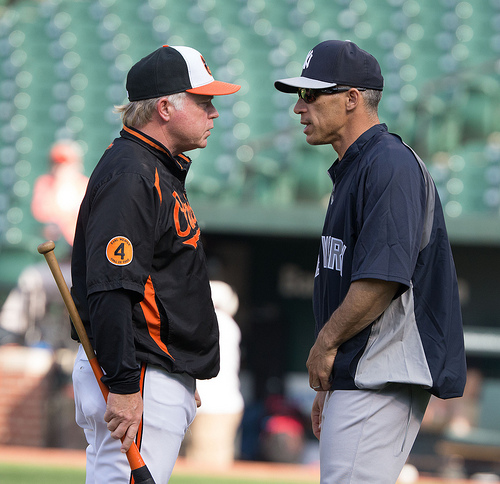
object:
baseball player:
[277, 38, 467, 482]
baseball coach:
[71, 44, 240, 482]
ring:
[300, 373, 345, 400]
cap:
[271, 28, 391, 100]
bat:
[25, 238, 136, 399]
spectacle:
[35, 141, 96, 196]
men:
[275, 11, 470, 484]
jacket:
[80, 137, 237, 360]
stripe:
[136, 262, 165, 366]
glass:
[291, 81, 333, 106]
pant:
[50, 334, 210, 483]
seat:
[204, 166, 303, 204]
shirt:
[23, 175, 100, 224]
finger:
[302, 374, 334, 394]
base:
[37, 239, 58, 262]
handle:
[24, 221, 92, 329]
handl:
[49, 342, 144, 451]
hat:
[123, 30, 244, 116]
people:
[255, 21, 471, 484]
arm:
[320, 233, 423, 352]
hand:
[294, 302, 365, 395]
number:
[90, 233, 147, 289]